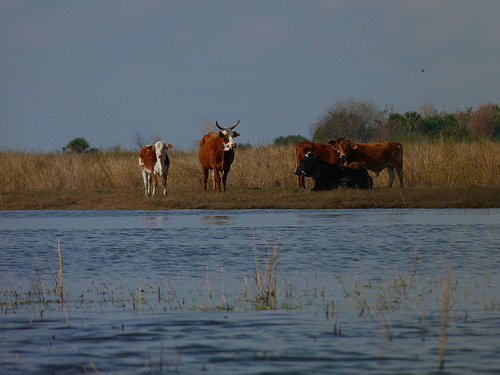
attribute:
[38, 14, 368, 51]
sky — blue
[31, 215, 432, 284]
water — blue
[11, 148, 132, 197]
grass — brown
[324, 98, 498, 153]
trees — green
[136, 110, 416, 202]
cows — brown, white, black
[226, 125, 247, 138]
ears — pointed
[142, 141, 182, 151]
ears — pointed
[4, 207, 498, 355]
ocean — beautiful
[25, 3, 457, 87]
sky — blue, clear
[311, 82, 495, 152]
trees — dark, brown, green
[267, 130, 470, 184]
reeds — placid blue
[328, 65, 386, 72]
airplane — large   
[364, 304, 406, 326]
ufo — top mid-right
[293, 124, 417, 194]
cows — clump of brown 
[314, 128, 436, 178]
clump — cattle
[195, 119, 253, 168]
expression — decidedly intent 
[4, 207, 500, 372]
water is blue — still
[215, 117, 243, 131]
horns sticking up — cow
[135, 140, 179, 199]
baby cow — brown, white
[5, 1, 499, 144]
blue sky — clear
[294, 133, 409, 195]
gang of cattle — gang 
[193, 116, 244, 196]
animal has horns — curious 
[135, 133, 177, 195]
young longhorn — new , uncertain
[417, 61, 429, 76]
small bird, — small  , mid-sized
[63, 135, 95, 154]
bushy tree — one, distance, left hand 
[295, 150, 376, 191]
darker animal sits — much 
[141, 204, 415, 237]
reflection of cows — fragile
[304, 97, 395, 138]
huge dry tree — huge dry 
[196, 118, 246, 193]
middle cattle figure —  figure 